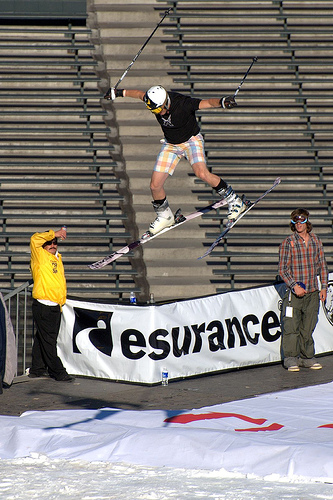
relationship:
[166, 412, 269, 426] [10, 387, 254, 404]
red stripe on bottom of cement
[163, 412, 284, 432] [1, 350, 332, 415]
red stripe on bottom of cement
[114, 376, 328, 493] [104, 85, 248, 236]
tarp beneath poles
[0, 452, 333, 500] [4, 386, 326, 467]
snow along ground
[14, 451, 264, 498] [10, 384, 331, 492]
snow on ground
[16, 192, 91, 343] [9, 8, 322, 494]
man watching event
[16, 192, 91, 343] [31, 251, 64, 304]
man in jacket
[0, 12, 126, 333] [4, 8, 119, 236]
empty bleachers in stands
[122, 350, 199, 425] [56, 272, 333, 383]
bottle standing in front of banner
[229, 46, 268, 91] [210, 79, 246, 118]
ski pole in hand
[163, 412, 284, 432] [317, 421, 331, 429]
red stripe on stripe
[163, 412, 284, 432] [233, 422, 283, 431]
red stripe on stripe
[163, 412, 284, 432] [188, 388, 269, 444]
red stripe on cement